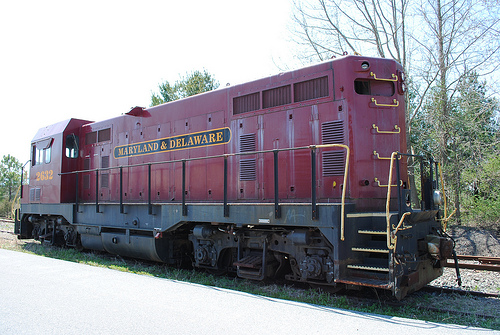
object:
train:
[13, 56, 453, 301]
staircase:
[334, 212, 401, 290]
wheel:
[204, 246, 234, 275]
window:
[32, 141, 54, 165]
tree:
[288, 0, 499, 228]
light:
[360, 61, 370, 72]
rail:
[57, 143, 354, 242]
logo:
[112, 126, 232, 160]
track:
[2, 245, 495, 333]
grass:
[0, 238, 499, 331]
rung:
[371, 96, 400, 108]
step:
[332, 274, 392, 289]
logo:
[35, 169, 55, 182]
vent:
[321, 119, 345, 145]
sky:
[1, 0, 269, 69]